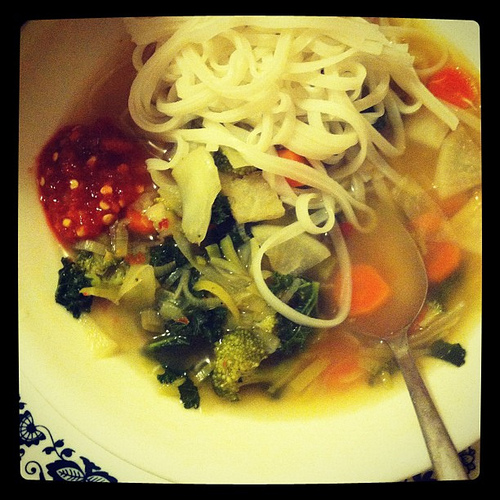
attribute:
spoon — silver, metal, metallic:
[325, 197, 470, 482]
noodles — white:
[118, 18, 461, 328]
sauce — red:
[28, 115, 158, 247]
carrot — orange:
[333, 263, 392, 316]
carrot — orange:
[423, 240, 462, 283]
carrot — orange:
[320, 339, 361, 388]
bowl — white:
[20, 17, 484, 483]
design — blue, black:
[21, 395, 120, 486]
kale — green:
[54, 257, 93, 318]